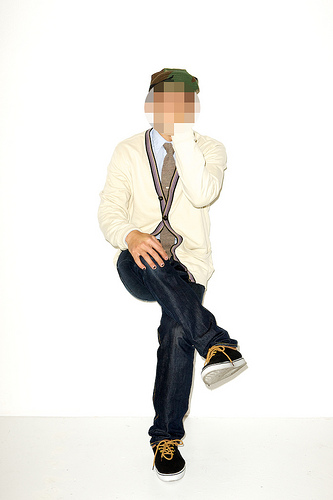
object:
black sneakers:
[150, 438, 185, 481]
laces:
[150, 437, 184, 469]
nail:
[161, 261, 164, 267]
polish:
[160, 264, 162, 266]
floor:
[0, 412, 328, 498]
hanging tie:
[160, 143, 175, 258]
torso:
[127, 128, 211, 256]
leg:
[117, 248, 220, 350]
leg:
[154, 280, 205, 432]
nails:
[164, 254, 168, 261]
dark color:
[143, 267, 146, 269]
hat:
[149, 67, 199, 89]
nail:
[153, 265, 157, 269]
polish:
[153, 266, 155, 268]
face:
[145, 76, 199, 137]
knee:
[145, 266, 187, 303]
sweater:
[98, 127, 228, 289]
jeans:
[117, 240, 238, 442]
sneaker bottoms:
[201, 359, 247, 389]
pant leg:
[148, 309, 194, 442]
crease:
[164, 337, 178, 435]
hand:
[164, 93, 189, 136]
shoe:
[200, 346, 246, 390]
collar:
[150, 128, 166, 153]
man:
[98, 68, 246, 481]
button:
[158, 194, 164, 200]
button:
[163, 213, 169, 222]